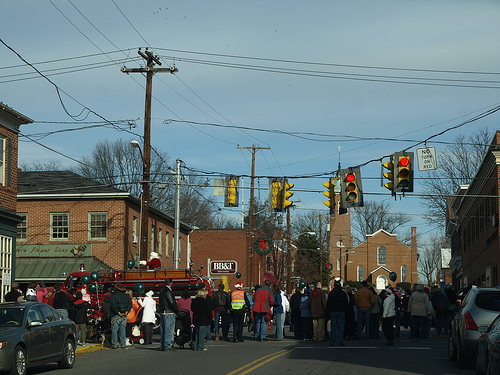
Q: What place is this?
A: It is a street.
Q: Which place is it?
A: It is a street.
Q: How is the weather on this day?
A: It is clear.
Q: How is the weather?
A: It is clear.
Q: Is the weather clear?
A: Yes, it is clear.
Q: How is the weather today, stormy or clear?
A: It is clear.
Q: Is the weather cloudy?
A: No, it is clear.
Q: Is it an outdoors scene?
A: Yes, it is outdoors.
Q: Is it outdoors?
A: Yes, it is outdoors.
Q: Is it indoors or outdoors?
A: It is outdoors.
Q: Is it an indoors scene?
A: No, it is outdoors.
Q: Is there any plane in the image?
A: No, there are no airplanes.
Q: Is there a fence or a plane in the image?
A: No, there are no airplanes or fences.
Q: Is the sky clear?
A: Yes, the sky is clear.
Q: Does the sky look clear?
A: Yes, the sky is clear.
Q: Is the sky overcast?
A: No, the sky is clear.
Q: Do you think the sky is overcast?
A: No, the sky is clear.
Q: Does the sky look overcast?
A: No, the sky is clear.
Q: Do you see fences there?
A: No, there are no fences.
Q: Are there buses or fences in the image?
A: No, there are no fences or buses.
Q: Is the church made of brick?
A: Yes, the church is made of brick.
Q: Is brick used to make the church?
A: Yes, the church is made of brick.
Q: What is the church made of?
A: The church is made of brick.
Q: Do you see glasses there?
A: No, there are no glasses.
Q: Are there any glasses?
A: No, there are no glasses.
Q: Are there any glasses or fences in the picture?
A: No, there are no glasses or fences.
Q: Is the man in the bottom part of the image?
A: Yes, the man is in the bottom of the image.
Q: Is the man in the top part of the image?
A: No, the man is in the bottom of the image.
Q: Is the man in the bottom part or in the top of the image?
A: The man is in the bottom of the image.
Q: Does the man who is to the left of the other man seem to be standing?
A: Yes, the man is standing.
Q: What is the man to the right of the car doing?
A: The man is standing.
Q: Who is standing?
A: The man is standing.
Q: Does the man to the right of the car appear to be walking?
A: No, the man is standing.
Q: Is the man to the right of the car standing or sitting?
A: The man is standing.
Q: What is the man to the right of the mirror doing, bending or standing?
A: The man is standing.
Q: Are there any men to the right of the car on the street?
A: Yes, there is a man to the right of the car.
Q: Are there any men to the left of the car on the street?
A: No, the man is to the right of the car.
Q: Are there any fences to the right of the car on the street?
A: No, there is a man to the right of the car.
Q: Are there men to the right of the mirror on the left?
A: Yes, there is a man to the right of the mirror.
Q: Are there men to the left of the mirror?
A: No, the man is to the right of the mirror.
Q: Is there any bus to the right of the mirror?
A: No, there is a man to the right of the mirror.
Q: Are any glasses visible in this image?
A: No, there are no glasses.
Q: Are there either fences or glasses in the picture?
A: No, there are no glasses or fences.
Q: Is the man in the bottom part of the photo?
A: Yes, the man is in the bottom of the image.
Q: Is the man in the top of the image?
A: No, the man is in the bottom of the image.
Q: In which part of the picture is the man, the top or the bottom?
A: The man is in the bottom of the image.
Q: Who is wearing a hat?
A: The man is wearing a hat.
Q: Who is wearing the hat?
A: The man is wearing a hat.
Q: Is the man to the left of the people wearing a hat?
A: Yes, the man is wearing a hat.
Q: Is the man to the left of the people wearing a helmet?
A: No, the man is wearing a hat.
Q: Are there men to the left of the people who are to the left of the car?
A: Yes, there is a man to the left of the people.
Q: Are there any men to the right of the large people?
A: No, the man is to the left of the people.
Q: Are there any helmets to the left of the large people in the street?
A: No, there is a man to the left of the people.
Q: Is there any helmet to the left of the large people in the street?
A: No, there is a man to the left of the people.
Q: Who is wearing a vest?
A: The man is wearing a vest.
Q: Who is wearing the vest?
A: The man is wearing a vest.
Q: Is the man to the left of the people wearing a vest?
A: Yes, the man is wearing a vest.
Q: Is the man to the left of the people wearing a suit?
A: No, the man is wearing a vest.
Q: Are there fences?
A: No, there are no fences.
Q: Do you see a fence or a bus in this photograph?
A: No, there are no fences or buses.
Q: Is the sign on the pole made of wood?
A: Yes, the sign is on the pole.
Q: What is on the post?
A: The sign is on the post.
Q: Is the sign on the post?
A: Yes, the sign is on the post.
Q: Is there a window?
A: Yes, there is a window.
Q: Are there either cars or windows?
A: Yes, there is a window.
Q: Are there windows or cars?
A: Yes, there is a window.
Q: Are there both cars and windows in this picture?
A: Yes, there are both a window and a car.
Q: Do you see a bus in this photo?
A: No, there are no buses.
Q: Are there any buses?
A: No, there are no buses.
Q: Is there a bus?
A: No, there are no buses.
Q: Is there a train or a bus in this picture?
A: No, there are no buses or trains.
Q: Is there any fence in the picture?
A: No, there are no fences.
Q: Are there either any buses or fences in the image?
A: No, there are no fences or buses.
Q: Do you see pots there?
A: No, there are no pots.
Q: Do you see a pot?
A: No, there are no pots.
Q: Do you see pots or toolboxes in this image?
A: No, there are no pots or toolboxes.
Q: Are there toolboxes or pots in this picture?
A: No, there are no pots or toolboxes.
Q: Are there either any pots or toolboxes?
A: No, there are no pots or toolboxes.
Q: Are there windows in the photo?
A: Yes, there is a window.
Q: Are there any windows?
A: Yes, there is a window.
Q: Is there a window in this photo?
A: Yes, there is a window.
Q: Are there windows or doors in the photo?
A: Yes, there is a window.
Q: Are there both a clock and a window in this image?
A: No, there is a window but no clocks.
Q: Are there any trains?
A: No, there are no trains.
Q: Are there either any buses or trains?
A: No, there are no trains or buses.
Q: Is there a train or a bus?
A: No, there are no trains or buses.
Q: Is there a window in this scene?
A: Yes, there is a window.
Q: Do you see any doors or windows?
A: Yes, there is a window.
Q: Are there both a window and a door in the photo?
A: Yes, there are both a window and a door.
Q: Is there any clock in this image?
A: No, there are no clocks.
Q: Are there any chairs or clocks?
A: No, there are no clocks or chairs.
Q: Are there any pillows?
A: No, there are no pillows.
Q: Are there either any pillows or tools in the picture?
A: No, there are no pillows or tools.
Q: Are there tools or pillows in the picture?
A: No, there are no pillows or tools.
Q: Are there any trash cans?
A: No, there are no trash cans.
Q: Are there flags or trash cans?
A: No, there are no trash cans or flags.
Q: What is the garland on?
A: The garland is on the pole.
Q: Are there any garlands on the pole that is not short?
A: Yes, there is a garland on the pole.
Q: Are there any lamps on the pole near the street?
A: No, there is a garland on the pole.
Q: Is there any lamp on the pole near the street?
A: No, there is a garland on the pole.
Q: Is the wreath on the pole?
A: Yes, the wreath is on the pole.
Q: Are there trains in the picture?
A: No, there are no trains.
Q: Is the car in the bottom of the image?
A: Yes, the car is in the bottom of the image.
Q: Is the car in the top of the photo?
A: No, the car is in the bottom of the image.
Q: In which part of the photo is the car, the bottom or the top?
A: The car is in the bottom of the image.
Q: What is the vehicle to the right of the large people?
A: The vehicle is a car.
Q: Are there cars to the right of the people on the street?
A: Yes, there is a car to the right of the people.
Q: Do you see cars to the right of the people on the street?
A: Yes, there is a car to the right of the people.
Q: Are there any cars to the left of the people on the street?
A: No, the car is to the right of the people.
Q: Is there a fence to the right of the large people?
A: No, there is a car to the right of the people.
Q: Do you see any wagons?
A: No, there are no wagons.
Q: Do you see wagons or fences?
A: No, there are no wagons or fences.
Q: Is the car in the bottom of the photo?
A: Yes, the car is in the bottom of the image.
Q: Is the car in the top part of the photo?
A: No, the car is in the bottom of the image.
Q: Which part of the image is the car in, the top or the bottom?
A: The car is in the bottom of the image.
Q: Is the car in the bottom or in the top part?
A: The car is in the bottom of the image.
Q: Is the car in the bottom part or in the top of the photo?
A: The car is in the bottom of the image.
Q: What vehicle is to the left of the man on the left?
A: The vehicle is a car.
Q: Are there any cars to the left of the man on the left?
A: Yes, there is a car to the left of the man.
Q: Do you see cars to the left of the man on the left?
A: Yes, there is a car to the left of the man.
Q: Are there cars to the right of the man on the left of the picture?
A: No, the car is to the left of the man.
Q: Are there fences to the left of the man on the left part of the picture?
A: No, there is a car to the left of the man.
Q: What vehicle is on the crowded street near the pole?
A: The vehicle is a car.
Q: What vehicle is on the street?
A: The vehicle is a car.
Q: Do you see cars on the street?
A: Yes, there is a car on the street.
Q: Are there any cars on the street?
A: Yes, there is a car on the street.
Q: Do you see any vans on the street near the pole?
A: No, there is a car on the street.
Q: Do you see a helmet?
A: No, there are no helmets.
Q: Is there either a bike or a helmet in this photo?
A: No, there are no helmets or bikes.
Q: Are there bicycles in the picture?
A: No, there are no bicycles.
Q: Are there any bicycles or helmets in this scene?
A: No, there are no bicycles or helmets.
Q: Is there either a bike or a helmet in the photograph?
A: No, there are no bikes or helmets.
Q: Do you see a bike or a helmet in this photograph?
A: No, there are no bikes or helmets.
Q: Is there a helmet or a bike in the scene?
A: No, there are no bikes or helmets.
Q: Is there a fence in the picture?
A: No, there are no fences.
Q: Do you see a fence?
A: No, there are no fences.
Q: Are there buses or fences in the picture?
A: No, there are no fences or buses.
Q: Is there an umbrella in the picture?
A: No, there are no umbrellas.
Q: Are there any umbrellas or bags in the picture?
A: No, there are no umbrellas or bags.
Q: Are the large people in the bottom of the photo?
A: Yes, the people are in the bottom of the image.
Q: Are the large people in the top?
A: No, the people are in the bottom of the image.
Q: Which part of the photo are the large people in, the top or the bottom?
A: The people are in the bottom of the image.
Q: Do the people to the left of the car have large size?
A: Yes, the people are large.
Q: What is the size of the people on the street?
A: The people are large.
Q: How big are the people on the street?
A: The people are large.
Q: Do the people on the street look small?
A: No, the people are large.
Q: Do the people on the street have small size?
A: No, the people are large.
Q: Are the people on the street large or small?
A: The people are large.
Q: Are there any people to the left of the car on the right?
A: Yes, there are people to the left of the car.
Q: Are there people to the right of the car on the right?
A: No, the people are to the left of the car.